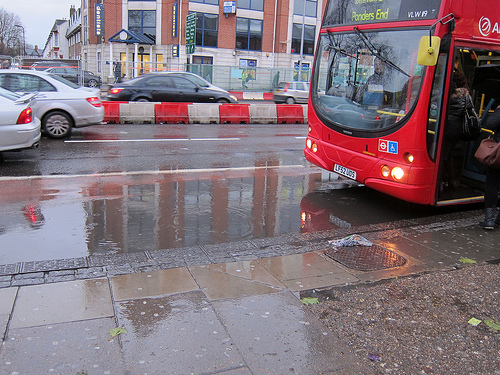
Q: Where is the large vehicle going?
A: Ponders End.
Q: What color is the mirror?
A: Yellow.